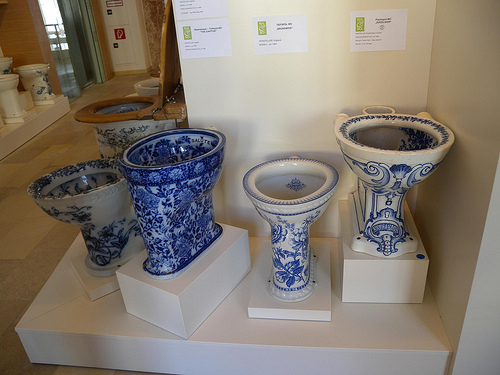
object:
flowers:
[137, 192, 162, 211]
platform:
[12, 219, 455, 374]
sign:
[110, 27, 125, 41]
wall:
[97, 0, 149, 78]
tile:
[0, 145, 46, 167]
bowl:
[333, 111, 456, 194]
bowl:
[241, 155, 339, 230]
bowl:
[112, 126, 227, 206]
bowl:
[25, 157, 131, 227]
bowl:
[90, 101, 174, 160]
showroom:
[0, 0, 499, 374]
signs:
[171, 0, 232, 21]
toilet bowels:
[13, 62, 53, 78]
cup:
[360, 104, 394, 117]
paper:
[347, 10, 405, 50]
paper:
[172, 18, 233, 60]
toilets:
[0, 72, 26, 126]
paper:
[250, 14, 311, 55]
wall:
[170, 0, 437, 239]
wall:
[406, 0, 498, 374]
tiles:
[0, 216, 59, 262]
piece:
[173, 15, 231, 58]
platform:
[68, 264, 119, 301]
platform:
[114, 220, 252, 340]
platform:
[245, 236, 330, 322]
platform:
[337, 200, 429, 303]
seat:
[71, 96, 159, 124]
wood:
[154, 0, 180, 116]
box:
[113, 221, 253, 340]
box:
[244, 236, 331, 324]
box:
[333, 195, 429, 304]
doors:
[56, 0, 95, 93]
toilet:
[332, 101, 456, 261]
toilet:
[240, 155, 341, 304]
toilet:
[114, 127, 227, 281]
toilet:
[26, 158, 148, 279]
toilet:
[72, 0, 191, 159]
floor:
[0, 70, 189, 374]